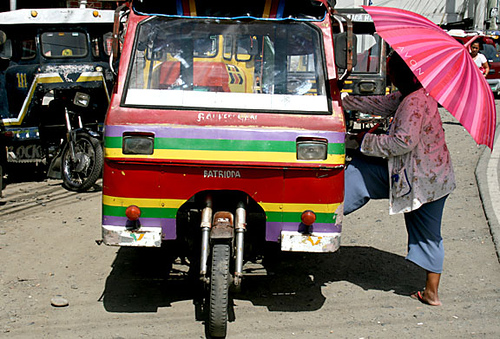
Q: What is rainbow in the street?
A: Scooter truck.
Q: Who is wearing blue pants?
A: The woman.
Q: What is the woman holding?
A: The umbrella.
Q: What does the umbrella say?
A: Avon.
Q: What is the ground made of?
A: Dirt.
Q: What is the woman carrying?
A: Pink umbrella.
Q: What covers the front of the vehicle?
A: Stripes.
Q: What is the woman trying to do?
A: Enter vehicle.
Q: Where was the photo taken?
A: City street.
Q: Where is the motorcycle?
A: Parked on street.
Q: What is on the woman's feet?
A: Flip flops.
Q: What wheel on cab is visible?
A: Front wheel.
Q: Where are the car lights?
A: On front.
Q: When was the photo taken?
A: In the daytime.q.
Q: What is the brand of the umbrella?
A: Avon.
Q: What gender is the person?
A: Female.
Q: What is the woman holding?
A: Umbrella.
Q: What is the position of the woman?
A: Standing.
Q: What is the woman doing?
A: Getting into a vehicle.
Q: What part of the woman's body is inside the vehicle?
A: Left leg.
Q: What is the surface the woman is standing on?
A: Dirt.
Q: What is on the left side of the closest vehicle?
A: Vehicles.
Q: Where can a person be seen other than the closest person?
A: Behind the umbrella.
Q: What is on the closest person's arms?
A: Sweater.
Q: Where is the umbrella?
A: Over the head of the closest woman.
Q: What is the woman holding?
A: Umbrella.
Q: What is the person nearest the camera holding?
A: Umbrella.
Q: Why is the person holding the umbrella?
A: Shade.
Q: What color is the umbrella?
A: Pink.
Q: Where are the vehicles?
A: Street.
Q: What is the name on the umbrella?
A: Avon.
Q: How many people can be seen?
A: Two.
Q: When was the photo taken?
A: Daytime.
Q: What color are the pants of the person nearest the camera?
A: Blue.